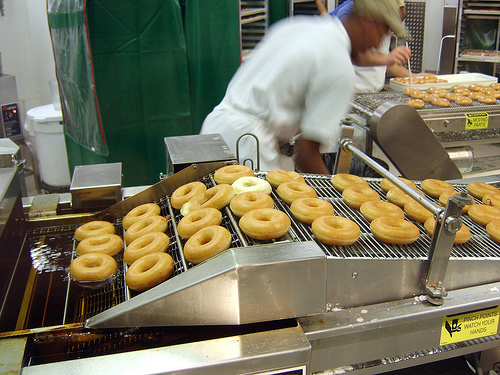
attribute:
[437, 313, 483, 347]
label — yellow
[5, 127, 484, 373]
machine — silver, metal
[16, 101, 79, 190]
container — white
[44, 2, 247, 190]
tent — plastic, green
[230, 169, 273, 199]
donut — white, single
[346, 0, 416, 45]
hat — brown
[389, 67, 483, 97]
container — white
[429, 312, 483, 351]
sticker — black, yellow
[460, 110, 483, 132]
sticker — yellow, black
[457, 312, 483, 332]
text — black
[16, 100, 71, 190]
trashcan — white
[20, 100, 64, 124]
lid — white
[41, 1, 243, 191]
curtain — green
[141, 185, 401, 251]
donuts — yellow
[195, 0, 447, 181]
people — cooking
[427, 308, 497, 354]
sign — yellow, safety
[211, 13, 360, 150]
baker — dressed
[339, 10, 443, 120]
person — glazing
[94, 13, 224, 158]
covering — green, plastic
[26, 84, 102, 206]
container — plastic, white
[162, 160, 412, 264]
doughnuts — grouped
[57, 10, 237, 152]
cover — green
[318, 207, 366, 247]
donut — glazed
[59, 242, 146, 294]
donut — glazed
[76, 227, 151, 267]
donut — glazed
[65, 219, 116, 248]
donut — glazed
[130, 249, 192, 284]
donut — glazed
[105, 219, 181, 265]
donut — glazed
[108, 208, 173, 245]
donut — glazed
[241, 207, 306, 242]
donut — glazed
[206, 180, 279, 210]
donut — glazed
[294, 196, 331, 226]
donut — glazed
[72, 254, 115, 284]
doughnut — golden brown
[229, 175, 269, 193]
doughnut — white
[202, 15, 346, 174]
outfit — white